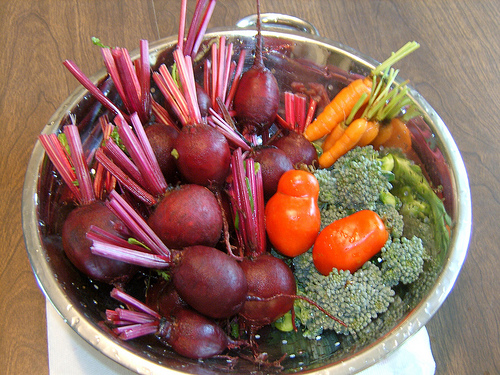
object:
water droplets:
[70, 317, 80, 327]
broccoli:
[292, 235, 426, 342]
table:
[0, 0, 498, 374]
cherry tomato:
[265, 168, 322, 257]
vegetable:
[37, 0, 436, 369]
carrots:
[302, 40, 421, 169]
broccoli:
[312, 144, 394, 212]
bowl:
[20, 12, 472, 374]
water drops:
[349, 236, 355, 243]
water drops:
[296, 216, 302, 220]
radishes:
[235, 0, 280, 138]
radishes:
[272, 92, 320, 171]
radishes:
[206, 95, 294, 193]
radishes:
[167, 0, 214, 117]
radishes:
[151, 48, 230, 185]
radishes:
[62, 39, 175, 171]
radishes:
[96, 111, 222, 247]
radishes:
[227, 146, 295, 367]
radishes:
[84, 189, 350, 328]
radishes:
[37, 124, 140, 283]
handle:
[236, 12, 320, 37]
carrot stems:
[361, 64, 411, 119]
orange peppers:
[311, 210, 392, 276]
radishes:
[105, 287, 263, 360]